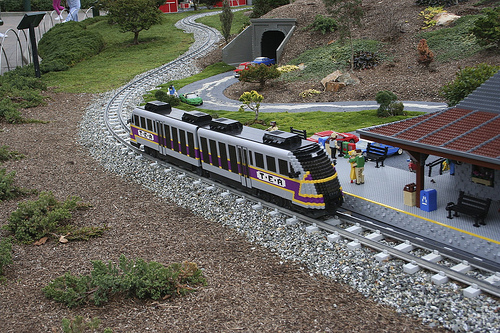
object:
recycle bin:
[420, 179, 436, 216]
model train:
[126, 99, 341, 217]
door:
[166, 2, 179, 14]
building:
[153, 0, 247, 15]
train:
[105, 89, 361, 211]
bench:
[445, 186, 494, 228]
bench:
[425, 156, 449, 179]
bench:
[288, 124, 308, 136]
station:
[353, 66, 497, 229]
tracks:
[340, 205, 498, 311]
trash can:
[403, 181, 418, 208]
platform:
[329, 146, 498, 240]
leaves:
[30, 229, 77, 250]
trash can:
[415, 180, 441, 214]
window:
[185, 132, 196, 155]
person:
[347, 144, 366, 184]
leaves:
[241, 88, 265, 104]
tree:
[227, 86, 281, 138]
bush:
[68, 260, 184, 301]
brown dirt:
[8, 87, 418, 330]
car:
[224, 56, 251, 85]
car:
[176, 90, 203, 109]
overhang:
[356, 105, 499, 169]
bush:
[413, 36, 436, 69]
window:
[199, 138, 234, 168]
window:
[261, 151, 281, 171]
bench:
[362, 139, 392, 169]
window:
[276, 158, 289, 178]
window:
[255, 155, 268, 170]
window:
[177, 128, 188, 153]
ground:
[8, 169, 218, 314]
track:
[108, 5, 498, 295]